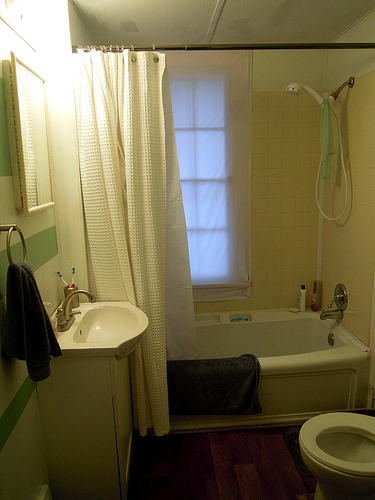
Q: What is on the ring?
A: Hand towel.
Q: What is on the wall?
A: Shower head.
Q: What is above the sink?
A: Medicine cabinet.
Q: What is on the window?
A: Plastic cover.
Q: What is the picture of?
A: Bathroom.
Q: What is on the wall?
A: Shower nozzle.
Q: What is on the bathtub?
A: Shampoo.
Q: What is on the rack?
A: Towel.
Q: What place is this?
A: Bathroom.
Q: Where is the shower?
A: Above the bath tub.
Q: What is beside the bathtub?
A: A window.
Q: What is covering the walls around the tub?
A: Tiles.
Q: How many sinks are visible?
A: One.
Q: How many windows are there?
A: One.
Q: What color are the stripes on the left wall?
A: Green.